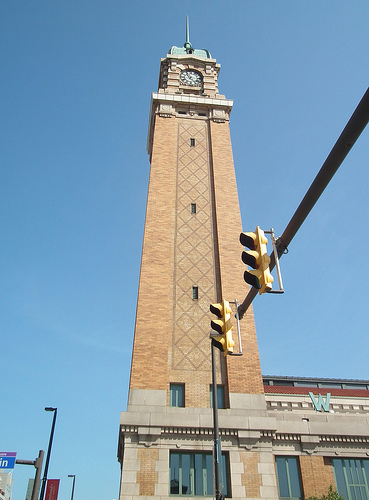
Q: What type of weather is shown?
A: Clear blue skies.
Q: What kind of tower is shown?
A: Clock tower.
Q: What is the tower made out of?
A: Brick.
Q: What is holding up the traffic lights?
A: A pole.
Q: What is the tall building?
A: A clock tower.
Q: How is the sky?
A: Clear.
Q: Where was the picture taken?
A: In the city.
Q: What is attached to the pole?
A: Traffic lights.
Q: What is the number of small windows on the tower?
A: Three.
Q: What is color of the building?
A: Tan.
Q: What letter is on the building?
A: W.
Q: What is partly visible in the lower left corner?
A: The street sign.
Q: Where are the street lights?
A: In the lower left corner.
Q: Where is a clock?
A: On the tower.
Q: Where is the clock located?
A: At the top of the tower.